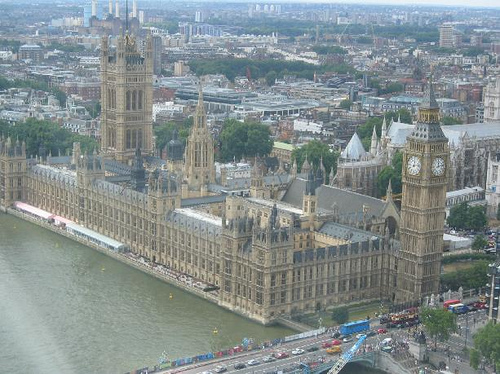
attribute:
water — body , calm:
[0, 209, 305, 371]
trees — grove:
[17, 112, 458, 162]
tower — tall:
[367, 52, 456, 368]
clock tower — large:
[399, 77, 444, 306]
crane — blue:
[326, 318, 377, 372]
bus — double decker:
[446, 295, 461, 305]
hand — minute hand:
[436, 158, 439, 168]